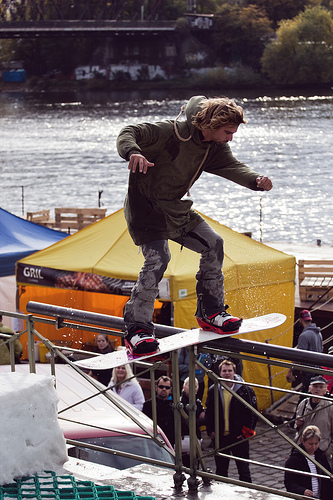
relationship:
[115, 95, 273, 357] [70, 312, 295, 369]
man on board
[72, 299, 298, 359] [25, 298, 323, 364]
board on rail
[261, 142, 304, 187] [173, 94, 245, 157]
water behind man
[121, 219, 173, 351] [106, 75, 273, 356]
leg on person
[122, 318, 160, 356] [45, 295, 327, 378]
boots on rail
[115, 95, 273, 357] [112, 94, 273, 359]
man watching snowboarder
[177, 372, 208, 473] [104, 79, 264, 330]
person watching snowboarder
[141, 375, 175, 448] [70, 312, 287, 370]
man watching board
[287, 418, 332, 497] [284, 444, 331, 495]
woman in coat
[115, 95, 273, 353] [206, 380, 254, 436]
man in jacket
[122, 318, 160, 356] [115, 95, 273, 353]
boots on man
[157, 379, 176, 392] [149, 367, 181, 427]
shades on man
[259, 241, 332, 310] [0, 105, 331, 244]
deck on water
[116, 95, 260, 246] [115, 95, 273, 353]
hoodie on man